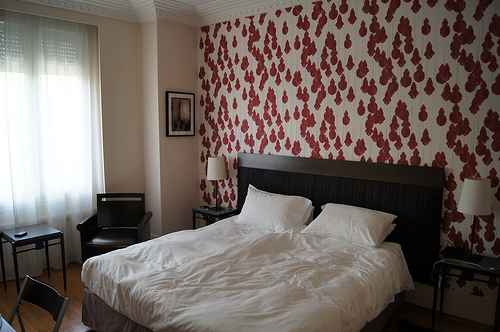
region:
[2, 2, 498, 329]
uncleaned hotel room with white sheer curtains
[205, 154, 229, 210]
small table lamp on the night stand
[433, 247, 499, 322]
night stand on the left of the bed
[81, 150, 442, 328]
white sheets and four white pillows on the bed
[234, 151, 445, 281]
black and brown headboard to the bed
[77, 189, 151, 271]
black chair set near the window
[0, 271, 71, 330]
desk chair set at the foot of the bed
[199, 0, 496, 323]
red and white wallpaper on one wall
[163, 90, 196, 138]
black framed art on the wall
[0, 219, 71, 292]
remote control sitting on a small table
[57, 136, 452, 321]
A bed set with white sheets.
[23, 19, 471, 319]
A bed set with white sheets in a room with red dotted wall paper.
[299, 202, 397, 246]
Pillow is white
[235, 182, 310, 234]
Pillow is white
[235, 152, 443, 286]
Headboard is made of wood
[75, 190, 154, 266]
brown chair next to the bed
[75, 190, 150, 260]
chair is made of wood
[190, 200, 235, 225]
nightstand next to the bed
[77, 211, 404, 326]
nightstand next to the bed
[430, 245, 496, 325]
nightstand next to the bed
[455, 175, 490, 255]
lamp on nightstand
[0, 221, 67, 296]
table next to the brown chair